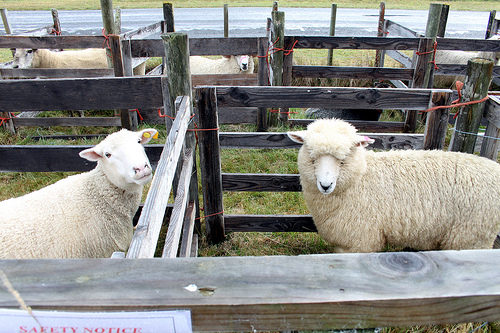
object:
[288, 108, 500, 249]
sheep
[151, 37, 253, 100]
sheep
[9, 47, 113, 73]
sheep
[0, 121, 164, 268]
sheep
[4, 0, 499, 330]
fence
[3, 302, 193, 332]
sign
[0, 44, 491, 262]
grass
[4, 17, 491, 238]
string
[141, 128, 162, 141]
tag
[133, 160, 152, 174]
nose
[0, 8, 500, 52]
water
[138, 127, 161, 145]
ear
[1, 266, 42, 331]
twine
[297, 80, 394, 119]
sheep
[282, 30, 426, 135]
gate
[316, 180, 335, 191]
nose